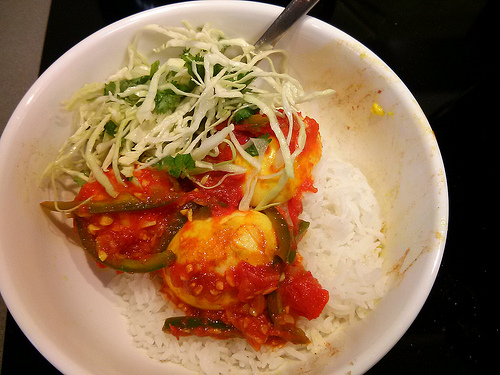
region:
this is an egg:
[167, 215, 287, 323]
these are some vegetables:
[72, 36, 301, 151]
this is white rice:
[312, 174, 371, 308]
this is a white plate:
[14, 3, 459, 372]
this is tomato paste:
[257, 306, 323, 370]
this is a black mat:
[371, 1, 492, 63]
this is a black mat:
[421, 5, 491, 370]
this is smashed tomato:
[92, 176, 164, 253]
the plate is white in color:
[384, 142, 448, 214]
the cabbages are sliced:
[127, 30, 267, 154]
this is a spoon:
[269, 1, 306, 33]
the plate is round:
[366, 107, 421, 163]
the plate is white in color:
[325, 197, 386, 259]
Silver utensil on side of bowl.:
[226, 20, 310, 59]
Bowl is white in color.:
[17, 138, 315, 365]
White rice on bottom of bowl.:
[308, 200, 361, 314]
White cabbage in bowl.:
[158, 76, 214, 144]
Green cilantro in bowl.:
[160, 82, 176, 121]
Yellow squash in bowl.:
[205, 227, 260, 306]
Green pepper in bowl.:
[78, 203, 167, 285]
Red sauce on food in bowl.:
[101, 199, 193, 271]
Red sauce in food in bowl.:
[296, 285, 341, 341]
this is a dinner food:
[23, 12, 454, 368]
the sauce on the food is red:
[97, 187, 322, 369]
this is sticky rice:
[315, 176, 370, 304]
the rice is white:
[310, 213, 365, 308]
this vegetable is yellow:
[165, 208, 281, 270]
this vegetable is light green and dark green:
[101, 83, 232, 148]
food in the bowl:
[105, 118, 358, 343]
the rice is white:
[330, 184, 366, 279]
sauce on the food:
[94, 160, 283, 276]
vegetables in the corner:
[74, 25, 274, 182]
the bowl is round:
[18, 135, 426, 356]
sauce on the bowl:
[332, 73, 426, 195]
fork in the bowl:
[253, 0, 313, 112]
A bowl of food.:
[20, 1, 450, 372]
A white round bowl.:
[32, 5, 443, 374]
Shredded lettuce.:
[65, 34, 309, 170]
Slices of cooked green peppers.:
[47, 194, 336, 268]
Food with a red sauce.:
[69, 119, 346, 338]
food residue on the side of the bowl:
[299, 37, 432, 373]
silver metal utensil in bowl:
[240, 2, 312, 60]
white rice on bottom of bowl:
[121, 145, 381, 362]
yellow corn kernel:
[365, 98, 390, 125]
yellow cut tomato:
[162, 202, 282, 319]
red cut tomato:
[71, 160, 189, 266]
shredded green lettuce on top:
[47, 17, 317, 179]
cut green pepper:
[43, 185, 167, 217]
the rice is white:
[108, 153, 384, 372]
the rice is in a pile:
[106, 153, 389, 374]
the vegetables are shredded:
[39, 19, 335, 210]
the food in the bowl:
[1, 0, 449, 373]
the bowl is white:
[0, 1, 450, 373]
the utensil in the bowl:
[0, 0, 448, 374]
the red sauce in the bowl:
[0, 0, 447, 374]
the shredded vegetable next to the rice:
[37, 18, 389, 373]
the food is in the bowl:
[1, 0, 448, 372]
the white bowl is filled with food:
[0, 0, 450, 372]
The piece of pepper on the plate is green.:
[72, 229, 174, 276]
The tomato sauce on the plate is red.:
[154, 213, 279, 299]